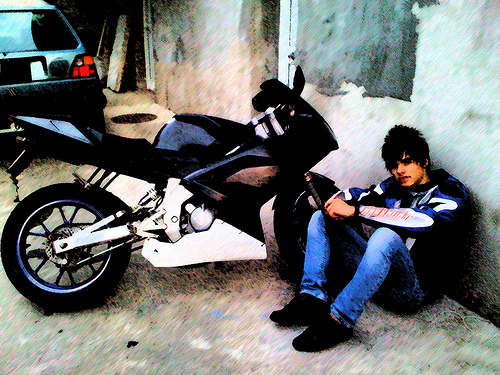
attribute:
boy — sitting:
[296, 123, 445, 373]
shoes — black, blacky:
[257, 285, 353, 359]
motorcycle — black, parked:
[10, 70, 332, 317]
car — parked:
[1, 5, 109, 131]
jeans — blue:
[287, 204, 427, 328]